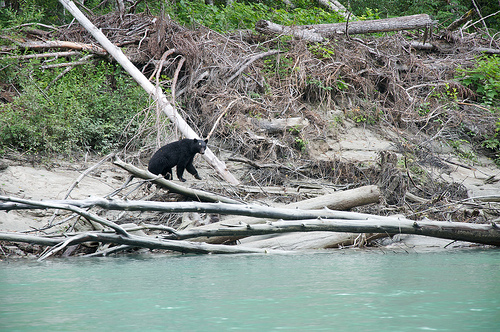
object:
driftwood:
[196, 46, 249, 113]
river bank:
[107, 205, 333, 241]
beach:
[33, 171, 93, 198]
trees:
[134, 24, 198, 54]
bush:
[172, 0, 250, 32]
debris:
[235, 28, 405, 99]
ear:
[193, 138, 197, 144]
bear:
[142, 138, 208, 191]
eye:
[204, 145, 207, 147]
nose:
[202, 148, 205, 154]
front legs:
[177, 160, 186, 181]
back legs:
[143, 165, 161, 191]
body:
[164, 150, 177, 163]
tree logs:
[0, 234, 140, 251]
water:
[183, 269, 389, 331]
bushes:
[0, 65, 129, 159]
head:
[194, 138, 210, 155]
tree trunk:
[107, 50, 156, 98]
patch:
[336, 133, 381, 160]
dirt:
[39, 171, 72, 193]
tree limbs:
[311, 161, 362, 192]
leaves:
[465, 68, 483, 95]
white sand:
[6, 215, 31, 228]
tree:
[0, 0, 69, 31]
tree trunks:
[113, 156, 187, 196]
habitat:
[55, 55, 432, 249]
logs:
[166, 200, 317, 221]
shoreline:
[69, 214, 196, 257]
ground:
[0, 168, 499, 247]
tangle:
[142, 46, 214, 65]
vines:
[296, 35, 350, 55]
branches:
[169, 40, 244, 81]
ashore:
[0, 108, 499, 195]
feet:
[179, 178, 186, 182]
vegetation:
[187, 6, 251, 24]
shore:
[45, 188, 114, 223]